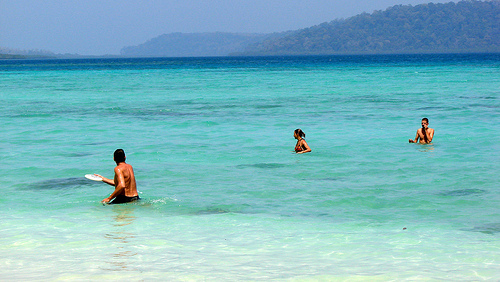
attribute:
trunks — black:
[112, 192, 135, 208]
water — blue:
[4, 61, 477, 256]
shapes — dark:
[15, 150, 488, 235]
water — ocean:
[358, 133, 468, 253]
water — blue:
[323, 65, 372, 98]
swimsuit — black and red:
[294, 141, 304, 152]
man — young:
[398, 108, 439, 152]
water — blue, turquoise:
[2, 52, 497, 279]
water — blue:
[294, 135, 422, 225]